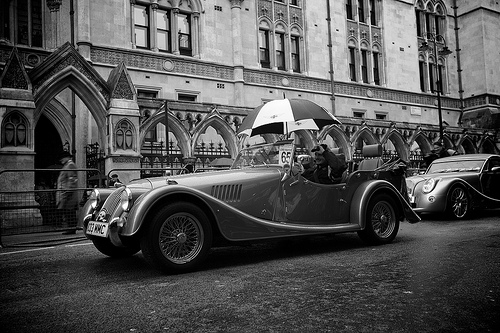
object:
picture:
[0, 0, 499, 332]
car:
[75, 139, 421, 274]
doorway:
[35, 114, 63, 195]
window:
[133, 4, 151, 49]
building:
[0, 0, 499, 230]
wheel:
[139, 198, 214, 272]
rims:
[157, 212, 205, 264]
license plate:
[84, 220, 111, 238]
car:
[405, 153, 499, 221]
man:
[312, 143, 349, 185]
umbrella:
[235, 92, 343, 143]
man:
[54, 150, 80, 235]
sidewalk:
[2, 229, 87, 263]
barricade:
[0, 168, 95, 240]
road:
[0, 209, 499, 332]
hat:
[55, 151, 74, 160]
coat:
[56, 161, 79, 209]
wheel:
[359, 189, 399, 245]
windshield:
[232, 144, 295, 169]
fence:
[81, 137, 425, 208]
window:
[258, 27, 272, 69]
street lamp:
[419, 32, 451, 139]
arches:
[1, 0, 500, 229]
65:
[281, 151, 290, 163]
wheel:
[447, 184, 471, 220]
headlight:
[120, 187, 133, 211]